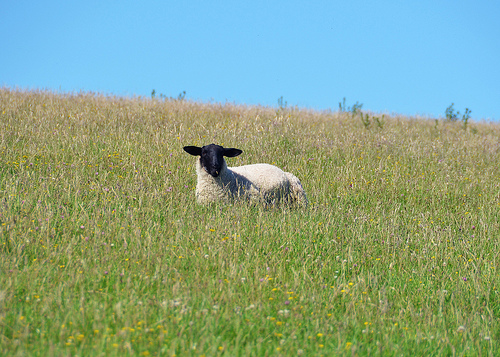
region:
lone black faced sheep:
[178, 128, 308, 231]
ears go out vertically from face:
[172, 139, 247, 159]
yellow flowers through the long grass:
[1, 275, 499, 355]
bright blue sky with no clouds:
[0, 5, 494, 115]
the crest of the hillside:
[5, 68, 497, 145]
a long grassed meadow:
[0, 90, 498, 355]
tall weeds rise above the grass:
[144, 80, 487, 138]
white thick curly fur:
[188, 168, 308, 212]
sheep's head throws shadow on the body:
[197, 138, 261, 213]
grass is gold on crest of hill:
[3, 88, 488, 162]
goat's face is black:
[169, 131, 241, 181]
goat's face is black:
[190, 143, 247, 179]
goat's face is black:
[179, 127, 258, 200]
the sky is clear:
[58, 40, 166, 75]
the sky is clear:
[296, 34, 383, 78]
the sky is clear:
[86, 22, 191, 58]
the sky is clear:
[261, 64, 373, 106]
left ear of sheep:
[219, 134, 240, 168]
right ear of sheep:
[169, 127, 201, 164]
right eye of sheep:
[192, 145, 210, 159]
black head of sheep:
[167, 104, 252, 185]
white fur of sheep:
[180, 165, 285, 210]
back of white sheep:
[273, 152, 319, 206]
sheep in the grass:
[160, 95, 327, 237]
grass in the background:
[322, 95, 462, 176]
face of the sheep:
[182, 133, 248, 181]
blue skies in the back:
[120, 31, 436, 98]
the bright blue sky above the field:
[2, 3, 499, 110]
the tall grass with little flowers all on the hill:
[8, 90, 494, 352]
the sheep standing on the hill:
[183, 143, 304, 206]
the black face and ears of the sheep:
[181, 143, 238, 175]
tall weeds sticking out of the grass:
[440, 103, 473, 127]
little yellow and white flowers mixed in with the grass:
[263, 282, 374, 355]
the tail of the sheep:
[290, 174, 307, 204]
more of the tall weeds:
[149, 87, 188, 102]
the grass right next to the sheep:
[204, 206, 304, 237]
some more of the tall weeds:
[358, 110, 388, 129]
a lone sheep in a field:
[158, 118, 373, 245]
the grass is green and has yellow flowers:
[107, 249, 337, 352]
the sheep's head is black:
[170, 118, 240, 220]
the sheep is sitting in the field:
[187, 117, 334, 250]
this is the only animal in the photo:
[147, 120, 331, 248]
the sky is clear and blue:
[11, 0, 489, 120]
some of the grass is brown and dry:
[21, 88, 496, 332]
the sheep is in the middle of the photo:
[163, 120, 354, 237]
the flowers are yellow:
[134, 298, 476, 354]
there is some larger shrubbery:
[311, 79, 498, 153]